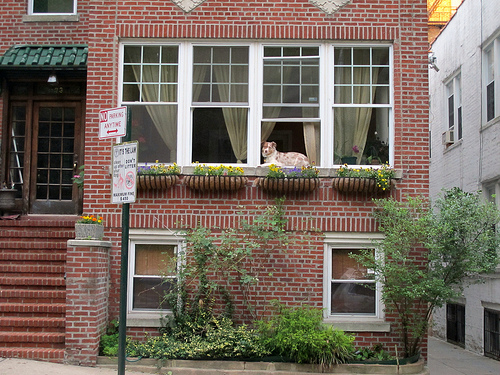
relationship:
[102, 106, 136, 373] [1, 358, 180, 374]
sign on street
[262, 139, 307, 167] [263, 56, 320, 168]
dog on window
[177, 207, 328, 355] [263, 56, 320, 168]
bushes near window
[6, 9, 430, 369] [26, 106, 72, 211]
building has door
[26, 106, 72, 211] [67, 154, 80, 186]
door has handle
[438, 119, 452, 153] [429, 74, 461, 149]
air conditioner in window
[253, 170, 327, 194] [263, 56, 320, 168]
flowers in front of window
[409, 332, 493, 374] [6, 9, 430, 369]
alley near building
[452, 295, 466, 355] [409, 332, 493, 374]
door near alley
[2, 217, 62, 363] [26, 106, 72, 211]
stairs near door